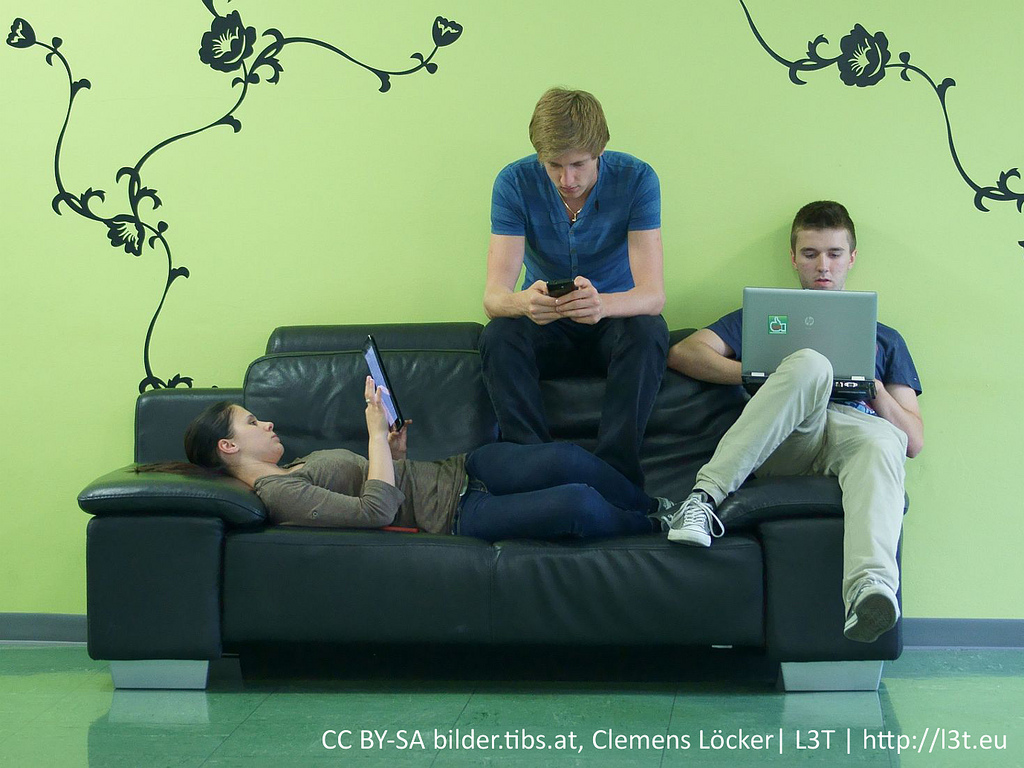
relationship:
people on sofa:
[187, 85, 922, 646] [73, 316, 912, 684]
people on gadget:
[128, 375, 684, 540] [353, 331, 405, 436]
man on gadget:
[666, 200, 923, 643] [729, 284, 892, 415]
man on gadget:
[477, 86, 671, 490] [547, 274, 579, 307]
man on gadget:
[653, 196, 917, 637] [740, 286, 875, 402]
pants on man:
[677, 348, 906, 637] [653, 196, 917, 637]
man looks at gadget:
[476, 82, 663, 466] [547, 278, 575, 298]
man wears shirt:
[476, 82, 663, 466] [478, 149, 671, 298]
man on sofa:
[477, 86, 671, 490] [73, 316, 912, 684]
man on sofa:
[666, 200, 923, 643] [73, 316, 912, 684]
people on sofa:
[128, 375, 684, 540] [73, 316, 912, 684]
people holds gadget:
[128, 375, 684, 540] [361, 334, 405, 433]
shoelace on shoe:
[658, 489, 728, 532] [661, 483, 723, 544]